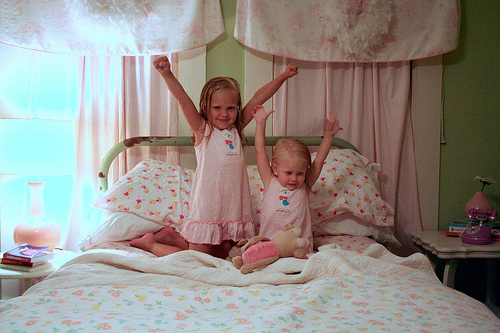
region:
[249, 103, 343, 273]
toddler sitting on a bed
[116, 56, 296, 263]
little girl sitting on a bed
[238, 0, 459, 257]
pink curtains covering a window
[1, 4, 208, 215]
pink curtains open on a window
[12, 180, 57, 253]
pink vase on a side table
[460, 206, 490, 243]
purple telephone on a side table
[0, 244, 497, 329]
pink floral quilt on a bed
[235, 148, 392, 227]
pink floral pillow cases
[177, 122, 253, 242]
pink dress on a girl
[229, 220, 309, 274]
pink teddy bear on a bed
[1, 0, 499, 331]
two small blond girls in bedroom with pink decor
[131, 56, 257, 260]
older blond girl in pink nightgown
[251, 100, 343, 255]
younger blond girl in pink nightgown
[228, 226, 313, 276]
teddy bear on bed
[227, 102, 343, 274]
teddy bear in front of younger girl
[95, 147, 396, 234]
pillows with pink and yellow design behind girls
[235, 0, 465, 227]
pink and white valance above window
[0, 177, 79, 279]
books and pink vase on round table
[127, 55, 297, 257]
small blond girl kneeling with outstretched arms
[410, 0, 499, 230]
white window frame next to green wall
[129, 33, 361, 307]
two childrens playing the bed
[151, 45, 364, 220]
two childrens raising hands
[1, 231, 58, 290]
some books kept in a table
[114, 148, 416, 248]
pillows kept in a bed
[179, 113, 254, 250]
a child wearing pink colour frock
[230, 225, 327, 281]
teddy bear kept in a bed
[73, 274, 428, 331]
a white colour flower design bedspread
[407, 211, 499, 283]
side table of the bed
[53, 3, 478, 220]
curtains behind the bed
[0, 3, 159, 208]
window of the bed room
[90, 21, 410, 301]
Two young ladies having fun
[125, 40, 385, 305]
Two young girls holding their arms up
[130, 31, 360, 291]
Two little girls wearing pink nightgowns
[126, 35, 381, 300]
Two little girls in their bedroom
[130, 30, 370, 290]
Two little girls on their bed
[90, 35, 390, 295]
Two little girls waking up in the morning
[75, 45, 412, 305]
A young girl and her sister are playing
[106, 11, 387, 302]
Two young people ready to start the day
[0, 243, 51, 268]
Books beside someone's bed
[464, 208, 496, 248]
Purple telephone beside someone's bed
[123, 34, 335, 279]
kids on the bed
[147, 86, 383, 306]
girls wearing pink dresses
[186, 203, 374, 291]
a stuffed toy on the bed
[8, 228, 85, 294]
books on the side table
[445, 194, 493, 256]
the telephone is pink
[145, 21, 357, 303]
the hands are raised up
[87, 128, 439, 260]
pillows on the bed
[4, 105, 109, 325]
a lamp on table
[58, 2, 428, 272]
the curtains are pink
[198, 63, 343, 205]
the hair are blonde